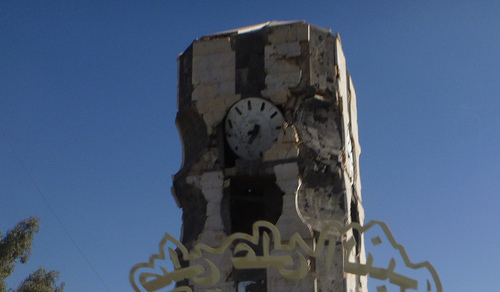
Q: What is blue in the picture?
A: The sky.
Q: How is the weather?
A: Sunny.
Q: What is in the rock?
A: A clock.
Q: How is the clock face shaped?
A: Like a circle.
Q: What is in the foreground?
A: A sculpture.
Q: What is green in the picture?
A: A tree.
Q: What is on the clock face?
A: Numeral markings.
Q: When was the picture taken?
A: Morning.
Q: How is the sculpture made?
A: Of metal.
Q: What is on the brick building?
A: A clock.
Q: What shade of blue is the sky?
A: Deep blue.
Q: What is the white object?
A: A fence.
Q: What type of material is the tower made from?
A: Brick.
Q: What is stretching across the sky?
A: A wire.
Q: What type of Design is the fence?
A: A Decorative design.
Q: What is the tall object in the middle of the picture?
A: A Clock tower.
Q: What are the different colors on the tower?
A: Brown and white.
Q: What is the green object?
A: A tree.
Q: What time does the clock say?
A: 7:45.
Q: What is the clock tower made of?
A: Stone.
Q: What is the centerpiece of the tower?
A: Clock.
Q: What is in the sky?
A: Nothing.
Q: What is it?
A: Clock.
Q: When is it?
A: Day time.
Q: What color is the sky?
A: Blue.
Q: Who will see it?
A: People.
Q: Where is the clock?
A: On the building.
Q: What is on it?
A: Cement.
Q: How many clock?
A: 1.